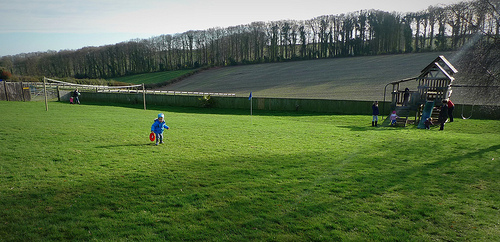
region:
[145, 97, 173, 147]
this is a baby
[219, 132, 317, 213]
this is a grass area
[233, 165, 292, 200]
the grass is green in color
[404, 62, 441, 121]
this is a structure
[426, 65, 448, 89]
the structure is made of woods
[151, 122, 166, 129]
this is a jacket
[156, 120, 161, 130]
the jacket is blue in color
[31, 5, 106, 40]
this is the sky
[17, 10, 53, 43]
the sky is blue in color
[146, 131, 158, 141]
this is a playing kite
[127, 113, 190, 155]
boy on green grass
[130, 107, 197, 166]
boy holds orange frisbee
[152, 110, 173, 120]
blue has blue hat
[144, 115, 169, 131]
boy has blue coat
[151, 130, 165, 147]
boy has blue pants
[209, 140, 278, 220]
grass is green and thick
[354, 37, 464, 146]
wooden playspace in background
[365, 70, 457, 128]
children are around playspace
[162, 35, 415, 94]
large hill behind children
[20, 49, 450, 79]
tall bare trees at top of hill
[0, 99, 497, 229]
Trimmed green grass ground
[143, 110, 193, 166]
Small child on green grass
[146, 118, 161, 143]
Red Frisbee in child's hand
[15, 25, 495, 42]
Treeline in the distance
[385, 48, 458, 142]
Jungle gym on right side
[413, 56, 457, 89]
Sloped roofs of jungle gym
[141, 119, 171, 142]
Blue coat on small child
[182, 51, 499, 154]
Sloping hill on opposite side of fence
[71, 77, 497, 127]
Green fence cutting through field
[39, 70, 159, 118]
Tennis net across field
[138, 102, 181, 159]
a small child in a field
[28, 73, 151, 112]
a volley ball net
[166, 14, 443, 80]
a row of trees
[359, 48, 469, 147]
children playing in a play house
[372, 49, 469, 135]
a wood play house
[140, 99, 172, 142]
a child holding a frisbee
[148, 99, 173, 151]
a child holding a red frisbee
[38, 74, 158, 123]
a volley ball net in a field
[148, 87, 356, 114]
a concrete wall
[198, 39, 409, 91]
a cut field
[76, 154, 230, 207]
well maintained green grass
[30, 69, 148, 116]
large white goal post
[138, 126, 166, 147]
red bag in girl's hand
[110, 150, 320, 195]
shadow on the green grass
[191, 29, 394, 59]
large forest of tall green trees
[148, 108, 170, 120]
blue cap on girl's head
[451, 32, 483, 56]
water spraying from the ground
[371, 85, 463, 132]
people standing on the grass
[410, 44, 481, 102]
wooden stands on the grass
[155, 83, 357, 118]
large green fence on side of grass